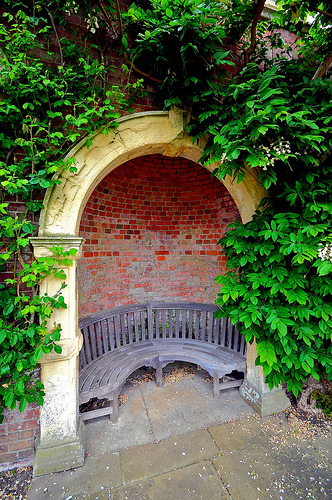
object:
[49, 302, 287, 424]
bench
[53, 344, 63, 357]
leaves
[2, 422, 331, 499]
petals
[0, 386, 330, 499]
walkway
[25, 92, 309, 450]
shelter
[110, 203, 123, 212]
bricks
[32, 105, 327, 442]
archway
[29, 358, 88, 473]
bottom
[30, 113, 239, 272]
discolored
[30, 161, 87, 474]
pillar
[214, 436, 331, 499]
stones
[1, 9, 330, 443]
wall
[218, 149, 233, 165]
flowers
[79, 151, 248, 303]
wall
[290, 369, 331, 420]
root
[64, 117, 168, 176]
paint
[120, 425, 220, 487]
slabs